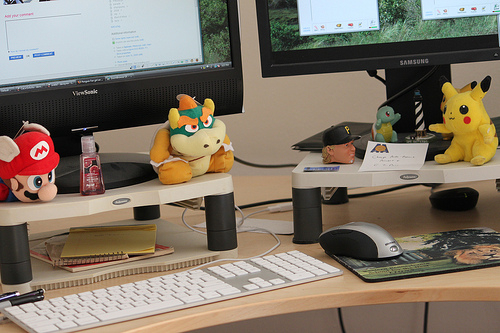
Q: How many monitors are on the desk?
A: 2.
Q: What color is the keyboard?
A: White.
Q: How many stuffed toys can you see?
A: 3.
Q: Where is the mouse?
A: To the right of the keyboard.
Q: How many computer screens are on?
A: Two.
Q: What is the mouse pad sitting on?
A: Desk.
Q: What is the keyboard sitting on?
A: Desk.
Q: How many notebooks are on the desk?
A: Three.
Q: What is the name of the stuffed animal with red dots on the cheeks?
A: Pikachu.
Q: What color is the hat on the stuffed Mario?
A: Red.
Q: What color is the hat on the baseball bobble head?
A: Black.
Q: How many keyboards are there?
A: One.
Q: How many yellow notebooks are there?
A: One.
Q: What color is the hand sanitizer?
A: Red.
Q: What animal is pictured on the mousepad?
A: Lion.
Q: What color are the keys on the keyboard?
A: White.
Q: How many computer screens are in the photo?
A: Two.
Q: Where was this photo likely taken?
A: An office.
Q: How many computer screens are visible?
A: Two.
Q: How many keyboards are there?
A: One.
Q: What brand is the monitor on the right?
A: Samsung.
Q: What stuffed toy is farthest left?
A: Mario.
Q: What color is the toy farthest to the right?
A: Yellow.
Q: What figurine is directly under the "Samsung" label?
A: A lighthouse.